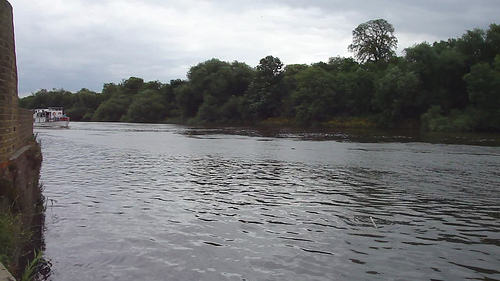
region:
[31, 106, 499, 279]
The water is rippling.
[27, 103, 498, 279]
The boat is in the water.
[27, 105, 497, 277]
The water is untroubled.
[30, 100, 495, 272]
The water is tranquil.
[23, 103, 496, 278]
The water is serene.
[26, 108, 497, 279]
The water is subdued.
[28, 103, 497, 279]
The water is mild.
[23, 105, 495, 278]
The water is mellow.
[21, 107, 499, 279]
The water is temperate.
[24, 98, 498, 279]
The water is placid.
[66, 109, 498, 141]
the shore line of a rive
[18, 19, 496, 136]
trees next to a river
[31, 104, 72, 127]
a boat going down the river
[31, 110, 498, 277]
a river filled with water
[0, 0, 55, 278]
a brick wall next to a river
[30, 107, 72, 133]
a white boat in the river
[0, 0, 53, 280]
a red brick wall by the river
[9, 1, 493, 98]
the sky that looks like it might rain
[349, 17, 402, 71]
a tall tree by the river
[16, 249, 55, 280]
plant growing next to a river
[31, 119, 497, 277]
Wide, calm river in countryside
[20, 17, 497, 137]
Green leaved trees growing along river bank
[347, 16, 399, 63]
Single tree that is much taller than others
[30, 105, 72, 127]
White boat on river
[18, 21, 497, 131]
Thickly forested river bank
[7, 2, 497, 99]
Sky covered in thick gray and white clouds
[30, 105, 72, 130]
Boat on river with bow facing camera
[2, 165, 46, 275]
Sheer bank below brick wall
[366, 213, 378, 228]
White stick or pole in water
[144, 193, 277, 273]
The water is calm.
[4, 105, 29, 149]
The building is made of brick.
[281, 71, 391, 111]
The trees in the background are green.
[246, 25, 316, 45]
The clouds are white.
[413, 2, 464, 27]
The sky is dark in color.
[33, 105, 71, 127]
The boat is white in color.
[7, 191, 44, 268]
The plants by the buliding are green.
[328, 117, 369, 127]
The flowers are yellow.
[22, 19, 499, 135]
Forest of trees near the river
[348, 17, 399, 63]
Tall green tree near the river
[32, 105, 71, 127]
White boat on the river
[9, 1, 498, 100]
Cloudy weather in the back ground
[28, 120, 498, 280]
A river of water near the trees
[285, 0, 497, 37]
Heavy cloud in the sky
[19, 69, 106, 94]
moderate cloud layer in the sky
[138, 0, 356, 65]
White cloud area in the sky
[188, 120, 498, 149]
Shadow of the trees on th water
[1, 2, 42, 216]
Building near the river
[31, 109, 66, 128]
A boat on the water.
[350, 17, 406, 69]
A tree in the woods.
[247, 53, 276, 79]
A tree in the woods.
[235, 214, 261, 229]
small ripple wave in murky river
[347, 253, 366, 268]
small ripple wave in murky river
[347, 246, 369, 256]
small ripple wave in murky river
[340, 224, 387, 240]
small ripple wave in murky river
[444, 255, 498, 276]
small ripple wave in murky river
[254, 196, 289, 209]
small ripple wave in murky river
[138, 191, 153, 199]
small ripple wave in murky river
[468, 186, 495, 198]
small ripple wave in murky river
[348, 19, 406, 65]
A tree in the woods.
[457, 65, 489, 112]
A tree in the woods.